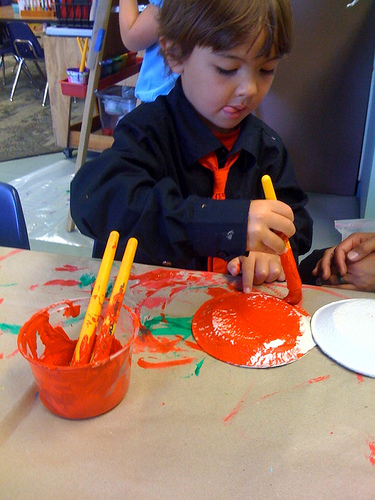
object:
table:
[0, 245, 374, 498]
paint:
[18, 297, 139, 420]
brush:
[97, 234, 133, 363]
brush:
[258, 173, 302, 299]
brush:
[73, 36, 89, 71]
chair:
[0, 179, 30, 248]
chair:
[5, 18, 50, 107]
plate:
[309, 296, 374, 381]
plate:
[191, 293, 316, 369]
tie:
[198, 150, 241, 274]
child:
[69, 0, 314, 297]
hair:
[159, 0, 293, 59]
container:
[67, 66, 90, 83]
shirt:
[70, 76, 314, 268]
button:
[214, 249, 229, 260]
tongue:
[222, 104, 236, 116]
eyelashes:
[214, 64, 238, 75]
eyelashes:
[260, 68, 276, 76]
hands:
[312, 231, 374, 294]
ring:
[336, 272, 346, 285]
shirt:
[208, 128, 242, 149]